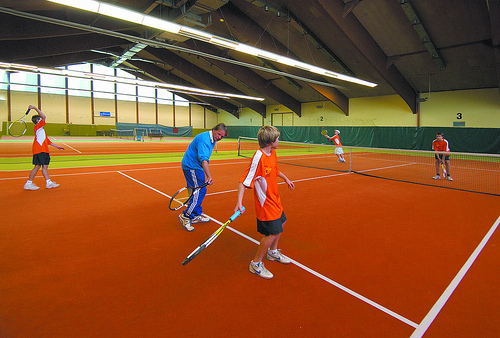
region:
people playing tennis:
[9, 90, 467, 274]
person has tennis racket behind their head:
[6, 105, 56, 196]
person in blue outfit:
[151, 126, 228, 226]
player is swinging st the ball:
[311, 121, 355, 168]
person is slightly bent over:
[424, 128, 460, 186]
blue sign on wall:
[88, 107, 129, 124]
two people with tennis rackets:
[164, 127, 303, 294]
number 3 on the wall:
[445, 108, 480, 133]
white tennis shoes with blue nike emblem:
[243, 243, 293, 281]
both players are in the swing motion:
[168, 114, 305, 279]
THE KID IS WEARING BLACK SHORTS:
[248, 202, 289, 238]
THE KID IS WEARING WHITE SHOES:
[241, 246, 294, 286]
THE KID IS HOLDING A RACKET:
[183, 205, 248, 270]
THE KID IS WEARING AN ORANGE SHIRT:
[235, 143, 281, 220]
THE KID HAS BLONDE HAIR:
[257, 122, 278, 147]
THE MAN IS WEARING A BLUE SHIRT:
[177, 127, 222, 172]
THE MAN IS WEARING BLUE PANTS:
[175, 158, 212, 223]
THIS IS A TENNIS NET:
[235, 131, 496, 202]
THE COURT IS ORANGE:
[1, 145, 496, 335]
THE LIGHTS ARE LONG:
[0, 5, 382, 97]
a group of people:
[21, 87, 481, 336]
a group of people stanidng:
[18, 95, 498, 326]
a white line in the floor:
[287, 262, 363, 319]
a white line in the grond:
[288, 247, 429, 332]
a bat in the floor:
[166, 228, 229, 272]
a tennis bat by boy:
[180, 211, 246, 273]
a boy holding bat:
[181, 215, 246, 274]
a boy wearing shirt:
[243, 150, 304, 216]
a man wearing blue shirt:
[165, 123, 220, 183]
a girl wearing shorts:
[28, 143, 74, 178]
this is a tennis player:
[224, 124, 307, 271]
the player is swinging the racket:
[239, 122, 295, 279]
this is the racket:
[174, 202, 244, 263]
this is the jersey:
[258, 157, 275, 209]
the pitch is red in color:
[326, 185, 431, 277]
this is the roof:
[374, 10, 441, 53]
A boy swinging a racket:
[181, 125, 300, 289]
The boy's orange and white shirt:
[241, 149, 288, 222]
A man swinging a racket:
[170, 122, 230, 228]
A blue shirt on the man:
[180, 128, 216, 171]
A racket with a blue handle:
[177, 204, 249, 264]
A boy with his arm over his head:
[8, 104, 62, 191]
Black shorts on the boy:
[31, 150, 50, 165]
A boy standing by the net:
[430, 131, 455, 181]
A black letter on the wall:
[455, 109, 464, 119]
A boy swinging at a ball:
[316, 123, 346, 162]